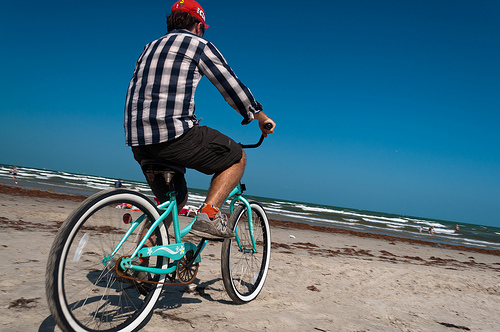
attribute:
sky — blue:
[288, 27, 465, 143]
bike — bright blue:
[45, 119, 271, 330]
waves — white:
[4, 165, 457, 236]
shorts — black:
[128, 123, 249, 213]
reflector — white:
[71, 229, 97, 263]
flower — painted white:
[174, 240, 189, 257]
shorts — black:
[120, 118, 247, 218]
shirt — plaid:
[111, 37, 289, 164]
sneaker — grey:
[194, 207, 236, 239]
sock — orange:
[202, 201, 219, 221]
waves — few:
[281, 199, 444, 229]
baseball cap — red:
[170, 0, 210, 27]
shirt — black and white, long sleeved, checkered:
[121, 31, 263, 148]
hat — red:
[182, 1, 208, 22]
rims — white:
[64, 220, 80, 249]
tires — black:
[50, 220, 63, 300]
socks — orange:
[207, 205, 215, 220]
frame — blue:
[166, 209, 178, 233]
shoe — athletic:
[191, 217, 219, 237]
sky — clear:
[4, 4, 484, 241]